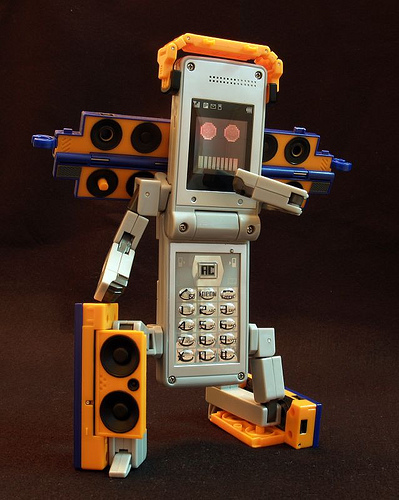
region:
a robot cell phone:
[78, 34, 380, 427]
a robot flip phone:
[63, 63, 374, 476]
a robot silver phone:
[78, 44, 367, 423]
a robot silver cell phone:
[89, 38, 369, 423]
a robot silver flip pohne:
[149, 12, 343, 356]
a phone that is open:
[81, 33, 294, 332]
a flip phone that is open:
[124, 53, 333, 377]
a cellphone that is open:
[105, 36, 301, 419]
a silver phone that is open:
[169, 62, 330, 460]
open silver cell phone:
[148, 49, 271, 392]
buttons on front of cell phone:
[169, 281, 244, 370]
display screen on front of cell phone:
[186, 92, 256, 204]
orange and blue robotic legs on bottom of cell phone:
[66, 298, 161, 481]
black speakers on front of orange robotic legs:
[90, 332, 144, 438]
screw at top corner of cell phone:
[182, 58, 199, 73]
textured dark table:
[4, 283, 393, 493]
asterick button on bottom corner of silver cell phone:
[173, 349, 194, 363]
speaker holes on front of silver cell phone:
[205, 68, 259, 91]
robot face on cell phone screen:
[196, 117, 245, 179]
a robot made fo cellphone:
[58, 16, 340, 496]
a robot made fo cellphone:
[38, 16, 365, 497]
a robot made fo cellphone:
[19, 41, 322, 485]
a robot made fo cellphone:
[31, 23, 319, 462]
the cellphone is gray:
[168, 49, 268, 411]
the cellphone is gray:
[152, 40, 276, 428]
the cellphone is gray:
[159, 43, 261, 398]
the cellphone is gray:
[147, 38, 258, 399]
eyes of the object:
[192, 99, 250, 153]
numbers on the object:
[169, 282, 247, 367]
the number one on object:
[176, 298, 198, 319]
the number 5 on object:
[194, 314, 215, 332]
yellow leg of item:
[65, 315, 155, 447]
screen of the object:
[190, 83, 266, 189]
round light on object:
[218, 114, 248, 151]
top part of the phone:
[179, 54, 260, 108]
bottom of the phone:
[150, 342, 264, 402]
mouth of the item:
[189, 147, 250, 180]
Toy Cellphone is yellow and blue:
[32, 37, 342, 459]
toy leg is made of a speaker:
[71, 292, 145, 490]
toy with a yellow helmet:
[151, 28, 282, 95]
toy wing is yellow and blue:
[19, 104, 344, 213]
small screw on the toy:
[236, 369, 246, 382]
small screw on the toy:
[178, 220, 187, 230]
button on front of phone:
[197, 283, 219, 301]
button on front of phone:
[219, 287, 236, 301]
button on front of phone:
[177, 303, 195, 316]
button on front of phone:
[199, 302, 216, 315]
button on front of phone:
[219, 302, 236, 315]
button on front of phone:
[177, 316, 194, 329]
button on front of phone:
[197, 316, 214, 330]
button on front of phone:
[219, 319, 237, 332]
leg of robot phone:
[68, 289, 158, 491]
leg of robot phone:
[63, 289, 170, 479]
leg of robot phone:
[59, 289, 163, 485]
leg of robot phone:
[60, 294, 163, 483]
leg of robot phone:
[60, 295, 171, 474]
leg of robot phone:
[70, 292, 171, 474]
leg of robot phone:
[63, 292, 167, 484]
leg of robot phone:
[59, 293, 167, 483]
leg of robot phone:
[59, 293, 175, 481]